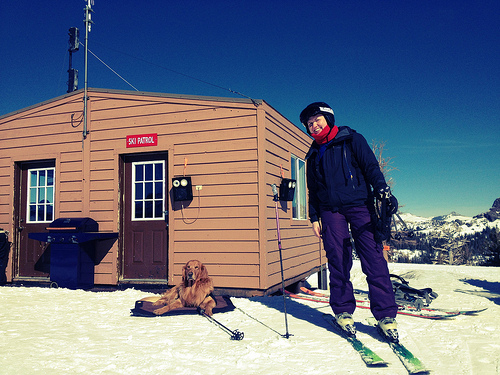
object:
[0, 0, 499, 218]
sky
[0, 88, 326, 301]
building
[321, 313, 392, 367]
skis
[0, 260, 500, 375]
ground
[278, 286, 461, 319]
skis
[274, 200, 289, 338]
ski pole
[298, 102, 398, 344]
person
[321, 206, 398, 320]
pants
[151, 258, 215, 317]
dog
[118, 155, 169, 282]
door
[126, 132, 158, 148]
sign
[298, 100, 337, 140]
head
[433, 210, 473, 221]
mountains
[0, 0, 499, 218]
background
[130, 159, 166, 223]
window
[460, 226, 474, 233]
snow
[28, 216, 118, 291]
grill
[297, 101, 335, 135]
helmet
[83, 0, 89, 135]
pole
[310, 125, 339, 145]
scarf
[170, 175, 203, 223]
meter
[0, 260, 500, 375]
snow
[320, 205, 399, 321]
ski clothes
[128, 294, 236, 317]
mat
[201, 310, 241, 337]
ski pole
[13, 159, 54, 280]
doors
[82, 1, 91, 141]
antennae